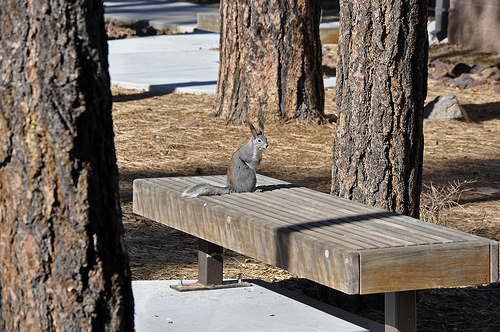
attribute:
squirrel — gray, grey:
[233, 134, 267, 196]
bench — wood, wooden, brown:
[255, 181, 484, 291]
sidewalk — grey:
[150, 289, 326, 327]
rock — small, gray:
[429, 92, 460, 118]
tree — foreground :
[6, 3, 120, 323]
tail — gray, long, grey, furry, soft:
[180, 180, 227, 196]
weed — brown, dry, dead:
[428, 175, 465, 217]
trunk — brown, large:
[342, 5, 425, 193]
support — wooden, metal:
[387, 293, 418, 324]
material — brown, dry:
[437, 135, 474, 161]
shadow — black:
[423, 158, 493, 176]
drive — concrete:
[117, 3, 196, 20]